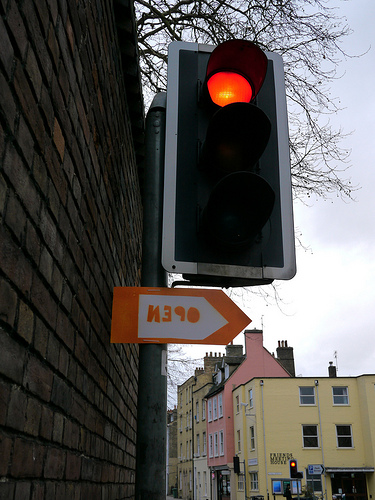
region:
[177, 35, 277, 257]
black traffic light on pole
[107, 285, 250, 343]
orange sign on pole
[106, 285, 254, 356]
orange arrow on pole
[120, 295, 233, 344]
white arrow on sign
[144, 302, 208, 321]
orange writing on sign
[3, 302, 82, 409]
brick wall next to pole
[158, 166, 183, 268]
white boarder of traffic light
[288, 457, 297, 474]
black traffic light on pole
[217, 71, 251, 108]
red light in traffic light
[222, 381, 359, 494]
yellow side of building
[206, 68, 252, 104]
A red light on the traffic light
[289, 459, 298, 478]
A traffic light by the building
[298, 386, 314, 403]
A window on the building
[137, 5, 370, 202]
A tree by the wall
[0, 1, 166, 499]
A wall by the traffic light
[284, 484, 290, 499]
A person standing by the traffic light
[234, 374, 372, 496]
A building by the traffic light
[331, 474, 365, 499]
Doors on the building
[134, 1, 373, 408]
The sky above the building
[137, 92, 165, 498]
A pole connected to the traffic light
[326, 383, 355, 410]
Small window on a building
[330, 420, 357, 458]
Small window on a building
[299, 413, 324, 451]
Small window on a building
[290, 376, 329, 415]
Small window on a building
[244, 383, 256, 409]
Small window on a building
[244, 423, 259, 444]
Small window on a building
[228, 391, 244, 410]
Small window on a building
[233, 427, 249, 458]
Small window on a building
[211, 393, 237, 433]
Small window on a building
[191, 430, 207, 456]
Small window on a building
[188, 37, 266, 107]
Red light on the traffic sign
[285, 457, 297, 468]
Red light on the traffic sign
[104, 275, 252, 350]
Arrow on a pole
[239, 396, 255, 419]
camera on the building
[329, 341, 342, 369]
antenna on the building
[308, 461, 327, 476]
Parking sign on the street pole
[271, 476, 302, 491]
advertisement in the window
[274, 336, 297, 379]
chimney on the building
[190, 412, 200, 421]
air conditioner in the window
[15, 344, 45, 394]
wall made of brick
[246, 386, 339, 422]
wall is yellow in color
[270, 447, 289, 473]
words are written in black color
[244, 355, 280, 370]
the wall is dull pink in color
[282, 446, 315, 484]
thestret light is beside the building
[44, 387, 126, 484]
the wall is red bricked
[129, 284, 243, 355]
the poster is aorange in color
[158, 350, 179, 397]
a white paper on th post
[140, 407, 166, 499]
the post is made of metal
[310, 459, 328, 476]
a white poster by the street